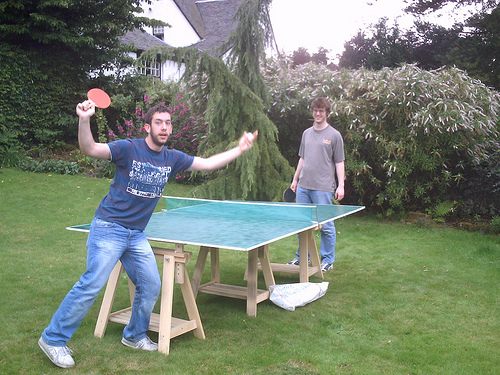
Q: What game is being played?
A: Ping pong.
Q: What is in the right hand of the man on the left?
A: Paddle.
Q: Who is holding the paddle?
A: The man on the left.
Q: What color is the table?
A: Green.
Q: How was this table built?
A: It was handmade.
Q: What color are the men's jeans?
A: Blue.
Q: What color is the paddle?
A: Red.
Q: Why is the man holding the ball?
A: He's getting ready to serve.